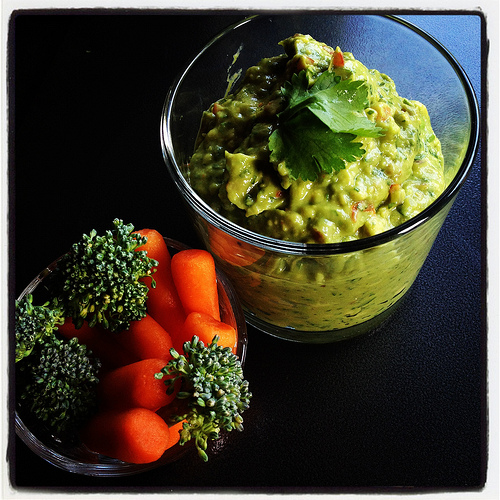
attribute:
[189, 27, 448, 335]
guacmole — chunky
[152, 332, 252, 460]
broccoli — green, florette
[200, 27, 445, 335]
guacamole — topped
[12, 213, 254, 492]
broccoli — uncooked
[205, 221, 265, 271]
reflections — carrot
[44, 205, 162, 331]
broccoli — discolored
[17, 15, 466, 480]
top — black, table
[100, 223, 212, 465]
baby carrots — orange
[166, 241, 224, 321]
carrot — baby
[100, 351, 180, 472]
carrots — uncooked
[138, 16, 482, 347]
bowl — glass